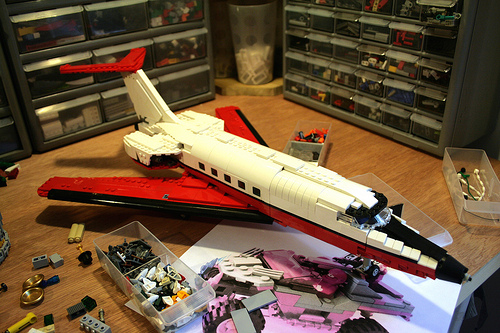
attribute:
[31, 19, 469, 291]
plane — air, red, lego, black, white, toy, area, section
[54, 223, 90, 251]
piece — lego, gray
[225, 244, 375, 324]
vehicle — pink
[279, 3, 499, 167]
box — gray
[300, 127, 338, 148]
lego — pink, gray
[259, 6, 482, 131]
shelve — gray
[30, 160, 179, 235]
wing — red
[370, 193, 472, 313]
nose — black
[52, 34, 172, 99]
tail — red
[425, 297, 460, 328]
paper — white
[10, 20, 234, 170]
cabinet — grey, large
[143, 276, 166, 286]
block — plastic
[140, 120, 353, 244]
toy — lego